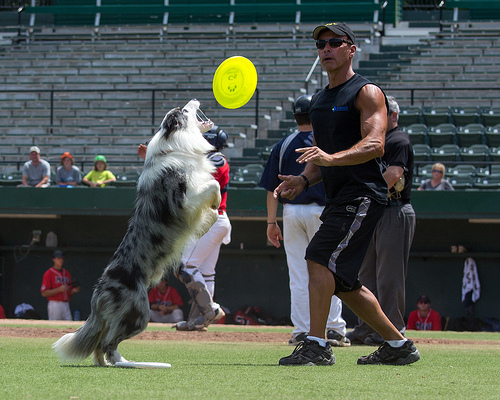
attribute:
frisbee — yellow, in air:
[212, 56, 258, 109]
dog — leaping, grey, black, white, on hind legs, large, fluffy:
[53, 95, 222, 367]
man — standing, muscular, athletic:
[273, 19, 420, 366]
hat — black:
[313, 22, 354, 46]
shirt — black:
[304, 72, 391, 205]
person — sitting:
[414, 161, 452, 191]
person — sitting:
[83, 151, 115, 187]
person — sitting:
[56, 152, 82, 188]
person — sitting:
[17, 146, 50, 188]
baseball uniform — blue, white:
[262, 129, 348, 335]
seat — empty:
[430, 123, 454, 142]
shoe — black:
[279, 338, 334, 365]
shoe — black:
[358, 338, 418, 365]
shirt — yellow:
[84, 170, 116, 185]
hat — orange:
[59, 150, 73, 160]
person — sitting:
[405, 290, 441, 329]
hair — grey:
[386, 94, 400, 122]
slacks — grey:
[344, 196, 415, 340]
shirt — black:
[381, 128, 415, 202]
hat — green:
[94, 151, 108, 166]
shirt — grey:
[55, 160, 82, 182]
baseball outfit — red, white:
[42, 264, 75, 320]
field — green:
[1, 318, 500, 400]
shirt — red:
[147, 284, 183, 310]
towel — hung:
[460, 256, 482, 302]